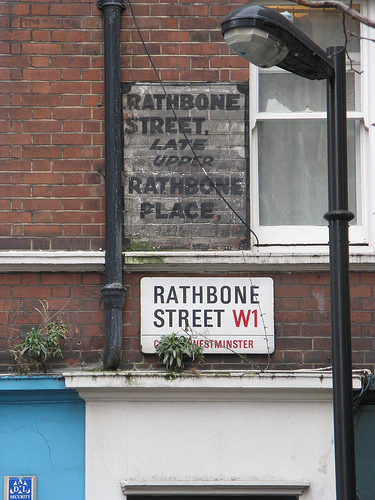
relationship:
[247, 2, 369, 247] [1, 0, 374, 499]
window on building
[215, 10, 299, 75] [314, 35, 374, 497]
light on pole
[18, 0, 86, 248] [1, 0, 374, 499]
bricks of building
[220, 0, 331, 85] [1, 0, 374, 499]
light beside building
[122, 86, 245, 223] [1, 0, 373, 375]
text written on building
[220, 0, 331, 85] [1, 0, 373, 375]
light near building